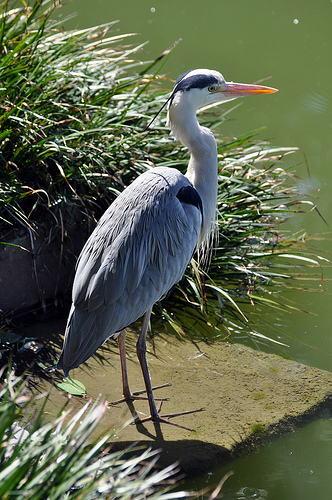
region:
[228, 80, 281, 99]
orange beak on a bird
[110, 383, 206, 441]
splayed talons on a bird's feet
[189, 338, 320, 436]
cement area where a bird stands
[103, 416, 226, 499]
shadow from a large bird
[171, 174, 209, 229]
black feathers in a bird's wing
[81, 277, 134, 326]
grey feathers on a bird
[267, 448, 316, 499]
murky green water by the shore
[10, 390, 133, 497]
green spiky grass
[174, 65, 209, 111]
white and black head of a bird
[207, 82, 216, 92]
yellow eye on a bird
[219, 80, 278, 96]
orange beek on bird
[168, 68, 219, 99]
bird has black streak on head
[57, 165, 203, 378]
bird has white feathers with black streak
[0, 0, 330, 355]
green bush behind bird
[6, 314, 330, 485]
bird standing on concrete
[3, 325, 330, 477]
slab of concrete partially in water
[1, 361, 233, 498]
green grass in front of bird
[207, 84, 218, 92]
bird has yellow eye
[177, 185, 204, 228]
bird with black streak on shoulder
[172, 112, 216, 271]
bird has long neck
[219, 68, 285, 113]
the beak is long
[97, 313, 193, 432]
the legs are skinny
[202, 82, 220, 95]
the eye is yellow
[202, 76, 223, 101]
the eye is open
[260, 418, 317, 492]
the water is green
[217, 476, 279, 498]
reflection in the water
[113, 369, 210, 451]
the feet are long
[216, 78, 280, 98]
the beak is orange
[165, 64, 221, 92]
the head is black and white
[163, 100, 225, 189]
the neck is white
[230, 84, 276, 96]
The beak of the bird.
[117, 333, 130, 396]
The left leg of the bird.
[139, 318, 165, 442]
The right leg of the bird.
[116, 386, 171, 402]
The left foot of the bird.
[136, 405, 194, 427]
The right foot of the bird.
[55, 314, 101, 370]
The tail feathers of the bird.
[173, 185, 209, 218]
The black feathers on the bird's body.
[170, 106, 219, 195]
The neck of the bird.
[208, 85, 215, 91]
The eye of the bird.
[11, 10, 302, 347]
The blades of grass behind the bird.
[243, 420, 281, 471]
edge of a shore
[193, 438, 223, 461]
part of a shade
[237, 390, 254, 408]
part of a ground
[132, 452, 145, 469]
aprt of a plnt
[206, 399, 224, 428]
part of a sansd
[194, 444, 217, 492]
part of a shade